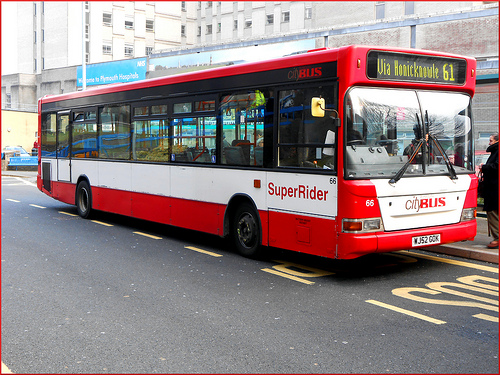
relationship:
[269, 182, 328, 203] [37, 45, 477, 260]
printing on bus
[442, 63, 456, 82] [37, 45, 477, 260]
number on bus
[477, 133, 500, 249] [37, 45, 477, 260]
person near bus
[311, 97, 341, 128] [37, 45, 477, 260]
mirror on bus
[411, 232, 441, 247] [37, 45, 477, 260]
plate on bus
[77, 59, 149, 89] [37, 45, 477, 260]
sign behind bus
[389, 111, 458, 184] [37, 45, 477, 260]
wipers on bus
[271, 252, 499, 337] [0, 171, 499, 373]
letters on street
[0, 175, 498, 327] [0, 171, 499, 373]
lines on street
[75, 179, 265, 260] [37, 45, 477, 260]
tires on bus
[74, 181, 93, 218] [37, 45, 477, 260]
tire on bus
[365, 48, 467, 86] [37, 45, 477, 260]
sign on bus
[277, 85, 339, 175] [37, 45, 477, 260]
window on bus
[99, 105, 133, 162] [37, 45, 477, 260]
window on bus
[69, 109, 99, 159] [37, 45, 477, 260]
window on bus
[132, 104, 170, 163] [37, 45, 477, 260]
window on bus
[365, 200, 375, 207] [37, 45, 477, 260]
numbers on bus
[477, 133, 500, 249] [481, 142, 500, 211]
person in coat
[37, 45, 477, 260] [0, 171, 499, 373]
bus on street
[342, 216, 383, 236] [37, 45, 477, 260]
lights on bus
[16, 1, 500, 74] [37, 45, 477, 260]
building behind bus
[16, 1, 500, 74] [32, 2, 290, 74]
building has windows